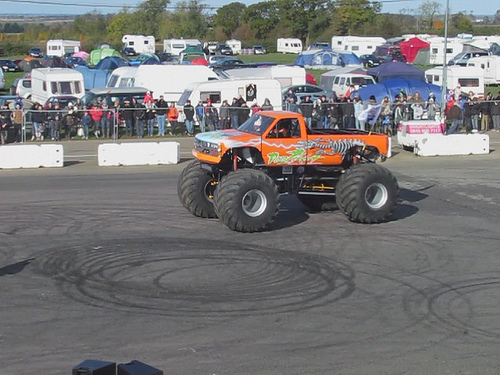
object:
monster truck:
[179, 108, 399, 235]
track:
[41, 235, 353, 314]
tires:
[337, 164, 399, 223]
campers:
[45, 39, 81, 56]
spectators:
[217, 100, 231, 129]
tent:
[400, 36, 428, 63]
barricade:
[97, 141, 180, 166]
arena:
[6, 169, 497, 362]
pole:
[444, 0, 448, 136]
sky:
[2, 1, 133, 24]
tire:
[215, 172, 281, 232]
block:
[0, 143, 65, 169]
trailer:
[422, 64, 485, 93]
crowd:
[299, 94, 492, 132]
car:
[284, 84, 338, 99]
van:
[166, 103, 179, 137]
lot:
[1, 31, 495, 66]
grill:
[193, 138, 219, 156]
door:
[263, 117, 307, 166]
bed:
[306, 131, 391, 167]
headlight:
[211, 144, 218, 150]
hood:
[193, 127, 260, 150]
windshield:
[235, 116, 269, 135]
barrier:
[416, 132, 491, 156]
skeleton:
[307, 138, 367, 155]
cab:
[192, 113, 309, 170]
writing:
[263, 150, 324, 165]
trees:
[340, 4, 374, 36]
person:
[157, 95, 170, 136]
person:
[65, 100, 77, 134]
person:
[481, 94, 492, 132]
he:
[182, 99, 195, 135]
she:
[90, 106, 101, 139]